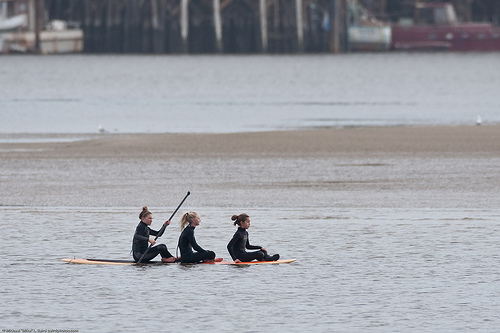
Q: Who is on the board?
A: Three women.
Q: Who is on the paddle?
A: Three girls.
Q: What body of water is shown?
A: The ocean.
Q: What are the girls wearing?
A: Wetsuits.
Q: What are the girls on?
A: A paddle board.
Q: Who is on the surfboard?
A: Three woman.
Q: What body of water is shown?
A: The ocean.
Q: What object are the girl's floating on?
A: A paddle board.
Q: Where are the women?
A: On a board.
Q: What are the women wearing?
A: Wet suits.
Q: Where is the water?
A: Under the women.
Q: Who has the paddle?
A: The last girl.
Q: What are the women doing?
A: Sitting.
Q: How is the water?
A: Calm.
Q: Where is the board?
A: In the water.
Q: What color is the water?
A: Brown.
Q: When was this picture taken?
A: During the day.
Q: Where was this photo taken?
A: In the water.